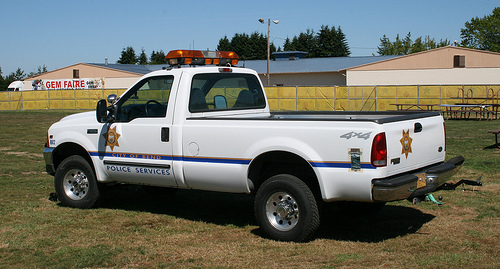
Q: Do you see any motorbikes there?
A: No, there are no motorbikes.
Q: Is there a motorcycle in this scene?
A: No, there are no motorcycles.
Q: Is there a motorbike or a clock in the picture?
A: No, there are no motorcycles or clocks.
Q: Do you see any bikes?
A: No, there are no bikes.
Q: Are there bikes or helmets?
A: No, there are no bikes or helmets.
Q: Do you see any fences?
A: Yes, there is a fence.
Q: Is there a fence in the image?
A: Yes, there is a fence.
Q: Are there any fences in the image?
A: Yes, there is a fence.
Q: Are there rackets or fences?
A: Yes, there is a fence.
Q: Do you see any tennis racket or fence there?
A: Yes, there is a fence.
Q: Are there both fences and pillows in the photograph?
A: No, there is a fence but no pillows.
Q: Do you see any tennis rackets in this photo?
A: No, there are no tennis rackets.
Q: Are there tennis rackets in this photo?
A: No, there are no tennis rackets.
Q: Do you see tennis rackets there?
A: No, there are no tennis rackets.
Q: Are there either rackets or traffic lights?
A: No, there are no rackets or traffic lights.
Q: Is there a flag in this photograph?
A: No, there are no flags.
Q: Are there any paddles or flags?
A: No, there are no flags or paddles.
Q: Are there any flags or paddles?
A: No, there are no flags or paddles.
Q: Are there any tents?
A: No, there are no tents.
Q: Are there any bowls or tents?
A: No, there are no tents or bowls.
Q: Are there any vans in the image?
A: No, there are no vans.